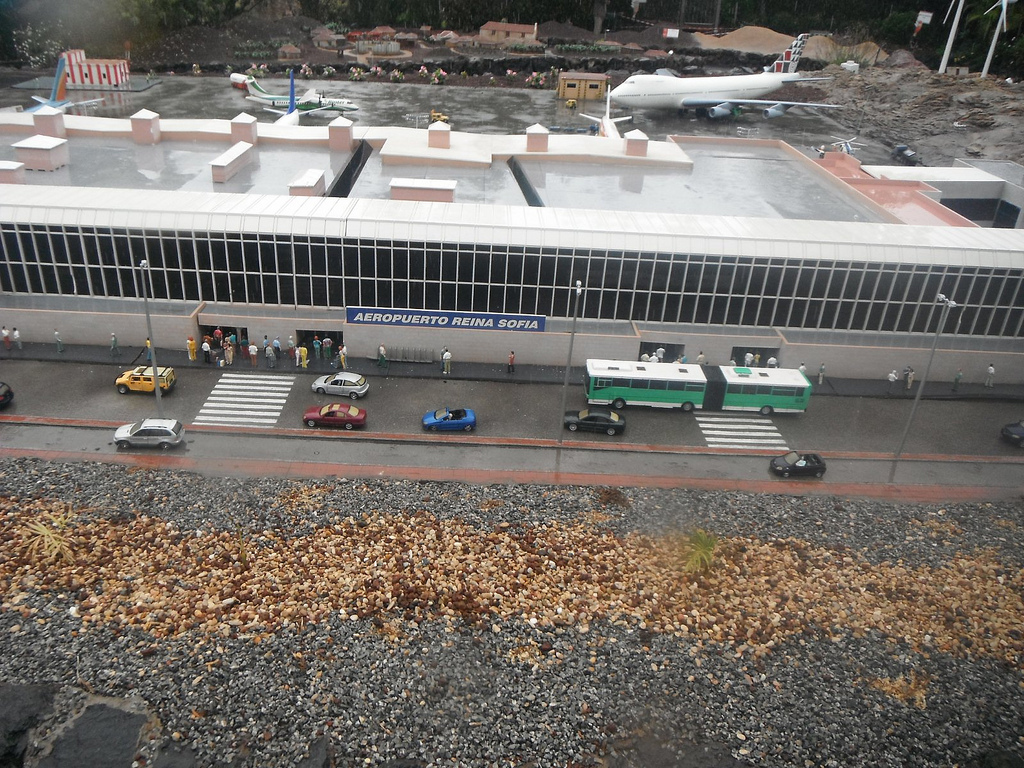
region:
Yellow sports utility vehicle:
[114, 363, 175, 402]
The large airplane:
[609, 26, 812, 121]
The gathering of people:
[180, 319, 354, 371]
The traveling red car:
[300, 402, 370, 431]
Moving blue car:
[413, 402, 484, 444]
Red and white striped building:
[57, 47, 131, 89]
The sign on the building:
[343, 306, 550, 333]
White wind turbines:
[936, 1, 1020, 81]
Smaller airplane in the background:
[230, 70, 360, 116]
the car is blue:
[422, 405, 479, 432]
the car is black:
[561, 405, 626, 434]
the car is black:
[772, 451, 824, 480]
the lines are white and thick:
[694, 407, 787, 452]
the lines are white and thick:
[190, 372, 295, 429]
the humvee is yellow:
[112, 361, 173, 396]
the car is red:
[301, 402, 365, 428]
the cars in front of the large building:
[1, 110, 1022, 477]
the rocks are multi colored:
[2, 456, 1021, 766]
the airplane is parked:
[608, 29, 842, 121]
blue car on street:
[413, 401, 486, 433]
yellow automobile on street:
[115, 362, 180, 398]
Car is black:
[766, 447, 834, 482]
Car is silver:
[109, 418, 186, 457]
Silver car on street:
[106, 401, 198, 469]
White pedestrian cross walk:
[184, 364, 301, 438]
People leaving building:
[195, 317, 354, 382]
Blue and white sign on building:
[343, 302, 555, 338]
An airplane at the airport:
[599, 38, 857, 128]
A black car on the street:
[565, 402, 627, 447]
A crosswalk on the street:
[188, 361, 294, 435]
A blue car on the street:
[414, 396, 481, 435]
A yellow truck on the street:
[110, 358, 178, 396]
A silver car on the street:
[295, 351, 371, 402]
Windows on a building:
[286, 231, 429, 321]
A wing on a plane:
[682, 86, 839, 124]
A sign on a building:
[343, 303, 559, 338]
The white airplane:
[600, 11, 839, 145]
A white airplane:
[587, 25, 848, 158]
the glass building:
[5, 120, 1021, 411]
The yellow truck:
[106, 344, 182, 396]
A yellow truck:
[102, 338, 207, 406]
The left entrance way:
[175, 311, 255, 369]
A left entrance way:
[176, 300, 260, 389]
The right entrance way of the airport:
[282, 305, 359, 373]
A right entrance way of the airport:
[283, 314, 369, 381]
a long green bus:
[569, 353, 832, 434]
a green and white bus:
[582, 358, 816, 416]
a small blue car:
[426, 405, 480, 437]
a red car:
[297, 402, 371, 428]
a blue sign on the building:
[344, 306, 542, 330]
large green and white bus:
[583, 352, 808, 413]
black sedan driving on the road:
[769, 444, 831, 477]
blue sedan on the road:
[421, 402, 479, 435]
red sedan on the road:
[296, 402, 366, 429]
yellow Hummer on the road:
[112, 365, 174, 389]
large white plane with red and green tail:
[604, 36, 832, 109]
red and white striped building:
[64, 45, 131, 83]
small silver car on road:
[311, 373, 387, 397]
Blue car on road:
[416, 405, 483, 435]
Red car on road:
[290, 401, 376, 436]